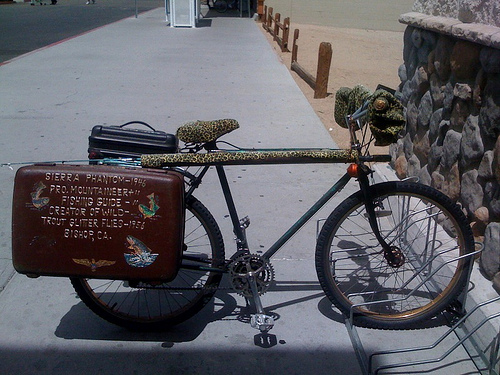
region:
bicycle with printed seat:
[7, 81, 487, 344]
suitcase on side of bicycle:
[4, 149, 182, 283]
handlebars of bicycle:
[327, 80, 411, 146]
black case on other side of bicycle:
[80, 117, 170, 171]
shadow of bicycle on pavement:
[55, 200, 419, 337]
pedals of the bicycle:
[228, 207, 283, 345]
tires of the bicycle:
[58, 168, 461, 330]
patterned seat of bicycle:
[174, 108, 238, 145]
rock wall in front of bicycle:
[387, 87, 499, 241]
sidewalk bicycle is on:
[5, 90, 440, 366]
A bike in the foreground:
[1, 66, 479, 349]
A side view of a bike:
[11, 85, 478, 351]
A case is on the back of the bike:
[10, 154, 190, 294]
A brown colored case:
[8, 161, 197, 298]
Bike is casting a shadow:
[46, 245, 454, 372]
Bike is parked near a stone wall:
[1, 86, 489, 357]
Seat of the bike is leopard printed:
[174, 103, 249, 157]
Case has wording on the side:
[18, 165, 161, 258]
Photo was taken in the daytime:
[4, 3, 491, 370]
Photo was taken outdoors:
[3, 3, 495, 373]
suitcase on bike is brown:
[4, 156, 182, 288]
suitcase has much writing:
[2, 152, 183, 287]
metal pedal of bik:
[248, 306, 269, 328]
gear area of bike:
[221, 249, 274, 296]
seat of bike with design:
[177, 118, 243, 145]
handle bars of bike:
[332, 86, 394, 111]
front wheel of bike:
[307, 173, 489, 333]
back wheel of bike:
[72, 198, 227, 325]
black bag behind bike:
[87, 115, 180, 165]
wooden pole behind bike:
[282, 31, 336, 97]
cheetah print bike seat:
[181, 116, 241, 149]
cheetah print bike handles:
[363, 85, 407, 154]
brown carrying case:
[23, 167, 184, 291]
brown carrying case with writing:
[13, 167, 177, 279]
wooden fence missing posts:
[258, 5, 335, 92]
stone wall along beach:
[396, 37, 493, 188]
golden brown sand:
[298, 10, 405, 79]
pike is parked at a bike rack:
[12, 104, 469, 348]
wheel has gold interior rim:
[296, 177, 471, 334]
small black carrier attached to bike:
[90, 119, 175, 163]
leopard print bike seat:
[171, 113, 241, 154]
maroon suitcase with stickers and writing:
[8, 160, 192, 287]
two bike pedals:
[218, 213, 285, 344]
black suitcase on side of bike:
[78, 115, 184, 180]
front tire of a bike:
[311, 178, 476, 334]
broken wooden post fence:
[246, 3, 338, 103]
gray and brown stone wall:
[381, 11, 498, 308]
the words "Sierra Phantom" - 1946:
[38, 164, 154, 189]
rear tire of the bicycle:
[58, 164, 227, 334]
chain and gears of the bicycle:
[116, 246, 277, 297]